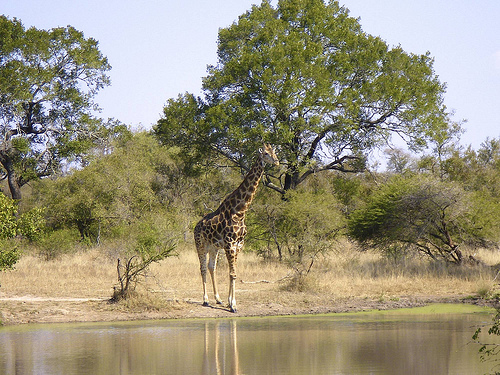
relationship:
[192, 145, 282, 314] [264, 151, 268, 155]
giraffe has eye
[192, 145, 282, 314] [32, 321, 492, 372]
giraffe on water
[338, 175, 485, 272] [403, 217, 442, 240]
tree has branch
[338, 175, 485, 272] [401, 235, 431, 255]
tree has branch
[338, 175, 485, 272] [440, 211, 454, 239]
tree has branch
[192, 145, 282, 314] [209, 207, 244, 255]
giraffe has patterns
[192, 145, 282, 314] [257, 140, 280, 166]
giraffe has head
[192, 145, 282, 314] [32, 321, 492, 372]
giraffe near water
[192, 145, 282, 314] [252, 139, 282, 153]
giraffe has horns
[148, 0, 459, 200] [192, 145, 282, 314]
green tree behind giraffe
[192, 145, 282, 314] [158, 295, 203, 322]
giraffe on top of dirt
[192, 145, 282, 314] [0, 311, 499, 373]
giraffe standing by water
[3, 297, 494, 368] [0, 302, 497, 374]
stream of water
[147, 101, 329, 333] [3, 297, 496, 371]
giraffe at water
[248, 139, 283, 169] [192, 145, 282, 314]
head of giraffe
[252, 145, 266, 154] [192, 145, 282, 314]
giraffe ear of giraffe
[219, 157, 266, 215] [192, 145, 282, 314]
neck of giraffe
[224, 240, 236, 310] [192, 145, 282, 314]
leg of giraffe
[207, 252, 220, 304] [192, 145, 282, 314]
back leg of giraffe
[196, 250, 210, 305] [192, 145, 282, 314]
back leg of giraffe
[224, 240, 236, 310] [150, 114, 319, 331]
leg of giraffe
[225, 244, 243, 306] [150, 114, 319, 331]
leg of giraffe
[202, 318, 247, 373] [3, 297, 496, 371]
reflection in water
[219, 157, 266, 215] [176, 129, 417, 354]
neck of giraffe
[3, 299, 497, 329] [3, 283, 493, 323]
moss growing on edge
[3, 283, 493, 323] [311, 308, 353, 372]
edge of water